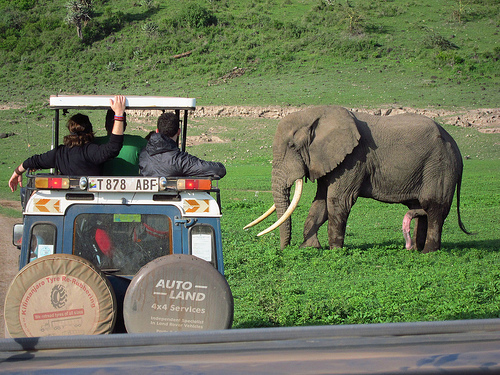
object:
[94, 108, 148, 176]
person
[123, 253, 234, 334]
wheel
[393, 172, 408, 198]
ground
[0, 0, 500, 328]
grass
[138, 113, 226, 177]
person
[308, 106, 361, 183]
ear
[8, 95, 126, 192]
people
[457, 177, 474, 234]
tail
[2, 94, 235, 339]
car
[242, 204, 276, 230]
tusks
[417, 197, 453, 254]
leg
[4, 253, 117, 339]
wheel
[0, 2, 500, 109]
hill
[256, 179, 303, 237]
tusks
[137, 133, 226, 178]
windbreaker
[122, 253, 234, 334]
wheel cover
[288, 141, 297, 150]
eye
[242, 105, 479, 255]
elephant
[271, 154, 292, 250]
trunk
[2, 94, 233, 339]
vehicle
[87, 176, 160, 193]
license tag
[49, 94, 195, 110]
top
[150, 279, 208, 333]
advertisement